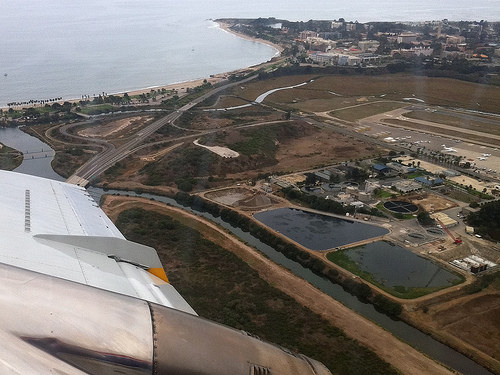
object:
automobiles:
[0, 161, 335, 373]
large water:
[0, 0, 500, 105]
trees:
[115, 191, 430, 375]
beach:
[0, 18, 285, 127]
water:
[0, 79, 500, 375]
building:
[414, 175, 446, 190]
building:
[391, 180, 424, 196]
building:
[369, 164, 393, 174]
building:
[337, 160, 359, 178]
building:
[312, 169, 339, 183]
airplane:
[477, 156, 488, 161]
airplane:
[441, 144, 458, 153]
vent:
[248, 362, 269, 375]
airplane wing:
[0, 166, 333, 373]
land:
[0, 17, 500, 375]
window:
[24, 227, 30, 232]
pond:
[325, 239, 466, 300]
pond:
[250, 206, 391, 252]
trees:
[225, 123, 284, 158]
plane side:
[0, 166, 333, 375]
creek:
[0, 125, 500, 375]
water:
[0, 0, 499, 108]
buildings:
[282, 22, 467, 67]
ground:
[0, 17, 497, 375]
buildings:
[301, 180, 378, 209]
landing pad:
[382, 200, 420, 214]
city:
[215, 13, 500, 375]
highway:
[65, 74, 260, 187]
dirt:
[101, 195, 464, 375]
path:
[102, 194, 455, 375]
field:
[0, 0, 500, 375]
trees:
[386, 140, 499, 226]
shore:
[1, 17, 500, 108]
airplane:
[0, 169, 334, 374]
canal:
[0, 124, 500, 374]